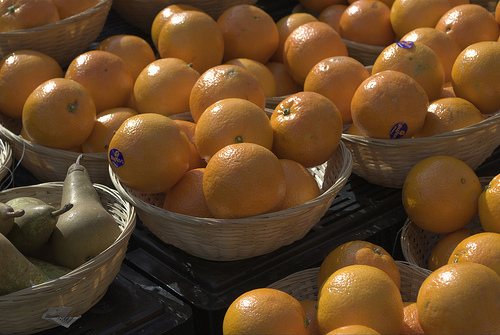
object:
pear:
[46, 153, 124, 272]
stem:
[74, 153, 85, 163]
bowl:
[0, 177, 138, 333]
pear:
[0, 224, 60, 295]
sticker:
[389, 122, 408, 140]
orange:
[131, 56, 202, 116]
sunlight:
[144, 63, 165, 78]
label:
[44, 306, 91, 333]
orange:
[202, 141, 286, 219]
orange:
[270, 91, 343, 169]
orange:
[194, 98, 275, 167]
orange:
[187, 64, 266, 125]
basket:
[103, 109, 360, 266]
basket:
[1, 178, 139, 333]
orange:
[350, 70, 430, 140]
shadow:
[315, 237, 362, 286]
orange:
[220, 287, 311, 334]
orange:
[315, 261, 406, 334]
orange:
[316, 240, 402, 299]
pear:
[2, 192, 73, 255]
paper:
[37, 302, 84, 332]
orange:
[107, 112, 190, 195]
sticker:
[105, 146, 130, 172]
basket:
[2, 122, 117, 188]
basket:
[340, 109, 500, 192]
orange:
[370, 40, 446, 103]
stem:
[66, 99, 78, 114]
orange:
[23, 78, 99, 149]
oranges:
[413, 261, 500, 335]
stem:
[50, 201, 72, 217]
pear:
[0, 195, 30, 238]